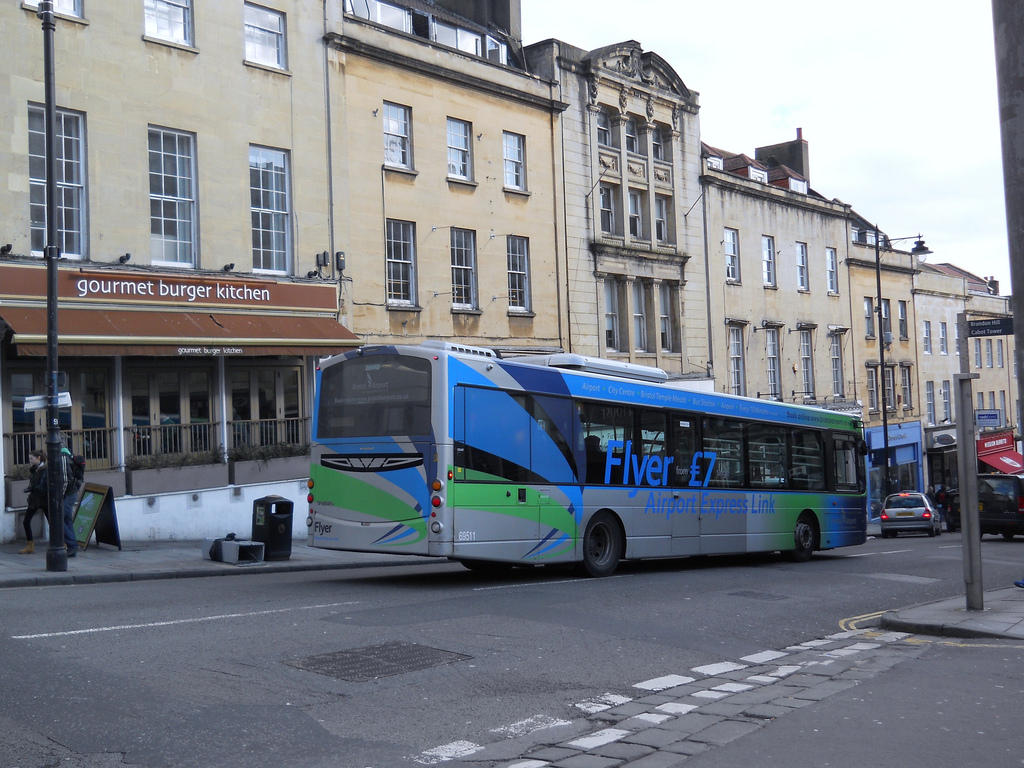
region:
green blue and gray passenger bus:
[298, 323, 912, 565]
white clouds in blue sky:
[681, 10, 748, 50]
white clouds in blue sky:
[851, 121, 916, 167]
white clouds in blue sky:
[924, 162, 973, 202]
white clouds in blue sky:
[718, 52, 773, 84]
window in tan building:
[378, 93, 416, 185]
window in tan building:
[377, 194, 444, 321]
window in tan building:
[500, 233, 536, 304]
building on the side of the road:
[699, 137, 861, 413]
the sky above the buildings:
[517, 1, 1018, 309]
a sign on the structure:
[59, 263, 306, 315]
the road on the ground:
[17, 579, 912, 753]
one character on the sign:
[70, 275, 89, 301]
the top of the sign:
[1, 249, 350, 295]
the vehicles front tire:
[787, 506, 823, 563]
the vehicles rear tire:
[570, 505, 629, 579]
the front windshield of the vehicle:
[820, 436, 860, 487]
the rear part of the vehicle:
[294, 333, 463, 571]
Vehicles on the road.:
[267, 335, 1013, 623]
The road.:
[1, 518, 1008, 766]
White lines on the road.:
[0, 532, 957, 757]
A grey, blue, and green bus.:
[315, 345, 872, 583]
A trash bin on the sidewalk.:
[246, 494, 295, 565]